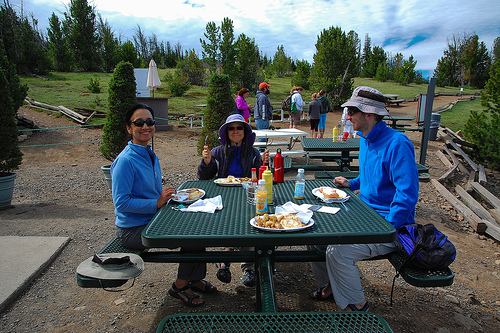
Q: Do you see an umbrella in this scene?
A: Yes, there is an umbrella.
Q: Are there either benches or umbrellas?
A: Yes, there is an umbrella.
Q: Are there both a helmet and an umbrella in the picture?
A: No, there is an umbrella but no helmets.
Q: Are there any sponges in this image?
A: No, there are no sponges.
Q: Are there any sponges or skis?
A: No, there are no sponges or skis.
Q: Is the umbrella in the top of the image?
A: Yes, the umbrella is in the top of the image.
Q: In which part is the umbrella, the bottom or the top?
A: The umbrella is in the top of the image.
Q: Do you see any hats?
A: Yes, there is a hat.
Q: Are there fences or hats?
A: Yes, there is a hat.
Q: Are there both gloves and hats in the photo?
A: No, there is a hat but no gloves.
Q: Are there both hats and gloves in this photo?
A: No, there is a hat but no gloves.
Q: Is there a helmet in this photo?
A: No, there are no helmets.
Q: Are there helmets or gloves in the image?
A: No, there are no helmets or gloves.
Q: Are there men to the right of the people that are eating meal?
A: Yes, there is a man to the right of the people.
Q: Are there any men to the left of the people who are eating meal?
A: No, the man is to the right of the people.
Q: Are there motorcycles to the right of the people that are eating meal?
A: No, there is a man to the right of the people.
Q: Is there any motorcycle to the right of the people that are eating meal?
A: No, there is a man to the right of the people.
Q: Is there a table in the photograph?
A: Yes, there is a table.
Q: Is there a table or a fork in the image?
A: Yes, there is a table.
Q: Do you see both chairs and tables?
A: No, there is a table but no chairs.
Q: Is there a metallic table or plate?
A: Yes, there is a metal table.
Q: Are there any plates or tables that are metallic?
A: Yes, the table is metallic.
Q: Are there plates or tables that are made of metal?
A: Yes, the table is made of metal.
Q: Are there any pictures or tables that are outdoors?
A: Yes, the table is outdoors.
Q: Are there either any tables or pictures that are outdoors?
A: Yes, the table is outdoors.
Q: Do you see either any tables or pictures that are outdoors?
A: Yes, the table is outdoors.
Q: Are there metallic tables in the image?
A: Yes, there is a metal table.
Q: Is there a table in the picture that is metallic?
A: Yes, there is a table that is metallic.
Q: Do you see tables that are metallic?
A: Yes, there is a table that is metallic.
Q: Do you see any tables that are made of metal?
A: Yes, there is a table that is made of metal.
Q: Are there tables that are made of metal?
A: Yes, there is a table that is made of metal.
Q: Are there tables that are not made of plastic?
A: Yes, there is a table that is made of metal.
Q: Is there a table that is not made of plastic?
A: Yes, there is a table that is made of metal.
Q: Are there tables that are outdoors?
A: Yes, there is a table that is outdoors.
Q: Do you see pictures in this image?
A: No, there are no pictures.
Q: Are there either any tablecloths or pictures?
A: No, there are no pictures or tablecloths.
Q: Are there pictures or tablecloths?
A: No, there are no pictures or tablecloths.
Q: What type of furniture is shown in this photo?
A: The furniture is a table.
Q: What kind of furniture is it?
A: The piece of furniture is a table.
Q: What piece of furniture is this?
A: This is a table.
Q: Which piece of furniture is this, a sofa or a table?
A: This is a table.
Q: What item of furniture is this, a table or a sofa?
A: This is a table.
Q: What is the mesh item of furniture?
A: The piece of furniture is a table.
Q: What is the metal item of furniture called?
A: The piece of furniture is a table.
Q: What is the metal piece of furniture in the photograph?
A: The piece of furniture is a table.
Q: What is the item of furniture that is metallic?
A: The piece of furniture is a table.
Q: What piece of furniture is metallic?
A: The piece of furniture is a table.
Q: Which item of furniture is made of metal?
A: The piece of furniture is a table.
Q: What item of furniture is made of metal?
A: The piece of furniture is a table.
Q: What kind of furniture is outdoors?
A: The furniture is a table.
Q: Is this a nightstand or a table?
A: This is a table.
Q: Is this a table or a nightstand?
A: This is a table.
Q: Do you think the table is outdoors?
A: Yes, the table is outdoors.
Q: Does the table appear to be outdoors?
A: Yes, the table is outdoors.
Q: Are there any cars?
A: No, there are no cars.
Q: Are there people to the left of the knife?
A: Yes, there are people to the left of the knife.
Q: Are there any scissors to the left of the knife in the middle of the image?
A: No, there are people to the left of the knife.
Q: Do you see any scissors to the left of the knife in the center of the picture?
A: No, there are people to the left of the knife.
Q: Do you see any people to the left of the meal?
A: Yes, there are people to the left of the meal.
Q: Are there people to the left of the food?
A: Yes, there are people to the left of the food.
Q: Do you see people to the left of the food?
A: Yes, there are people to the left of the food.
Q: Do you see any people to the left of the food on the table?
A: Yes, there are people to the left of the food.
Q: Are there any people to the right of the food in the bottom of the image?
A: No, the people are to the left of the food.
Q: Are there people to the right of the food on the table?
A: No, the people are to the left of the food.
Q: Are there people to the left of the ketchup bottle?
A: Yes, there are people to the left of the bottle.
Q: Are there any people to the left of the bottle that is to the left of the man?
A: Yes, there are people to the left of the bottle.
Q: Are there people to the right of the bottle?
A: No, the people are to the left of the bottle.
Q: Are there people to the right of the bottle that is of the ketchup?
A: No, the people are to the left of the bottle.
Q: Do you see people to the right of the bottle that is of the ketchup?
A: No, the people are to the left of the bottle.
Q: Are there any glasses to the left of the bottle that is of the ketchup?
A: No, there are people to the left of the bottle.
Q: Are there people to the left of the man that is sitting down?
A: Yes, there are people to the left of the man.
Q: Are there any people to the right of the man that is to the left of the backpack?
A: No, the people are to the left of the man.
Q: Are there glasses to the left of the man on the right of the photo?
A: No, there are people to the left of the man.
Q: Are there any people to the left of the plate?
A: Yes, there are people to the left of the plate.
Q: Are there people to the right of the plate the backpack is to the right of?
A: No, the people are to the left of the plate.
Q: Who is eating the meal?
A: The people are eating the meal.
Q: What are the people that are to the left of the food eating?
A: The people are eating meal.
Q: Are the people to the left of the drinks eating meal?
A: Yes, the people are eating meal.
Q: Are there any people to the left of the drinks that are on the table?
A: Yes, there are people to the left of the drinks.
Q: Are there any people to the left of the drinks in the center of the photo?
A: Yes, there are people to the left of the drinks.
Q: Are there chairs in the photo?
A: No, there are no chairs.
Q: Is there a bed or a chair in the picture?
A: No, there are no chairs or beds.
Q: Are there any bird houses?
A: No, there are no bird houses.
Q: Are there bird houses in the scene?
A: No, there are no bird houses.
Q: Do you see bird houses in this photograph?
A: No, there are no bird houses.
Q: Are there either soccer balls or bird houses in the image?
A: No, there are no bird houses or soccer balls.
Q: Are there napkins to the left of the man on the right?
A: Yes, there is a napkin to the left of the man.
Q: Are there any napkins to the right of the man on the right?
A: No, the napkin is to the left of the man.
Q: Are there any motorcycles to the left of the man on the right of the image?
A: No, there is a napkin to the left of the man.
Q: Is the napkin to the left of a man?
A: Yes, the napkin is to the left of a man.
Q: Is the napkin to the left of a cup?
A: No, the napkin is to the left of a man.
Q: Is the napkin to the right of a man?
A: No, the napkin is to the left of a man.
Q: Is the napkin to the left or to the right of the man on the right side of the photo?
A: The napkin is to the left of the man.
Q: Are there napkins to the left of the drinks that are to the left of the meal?
A: Yes, there is a napkin to the left of the drinks.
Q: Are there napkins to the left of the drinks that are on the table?
A: Yes, there is a napkin to the left of the drinks.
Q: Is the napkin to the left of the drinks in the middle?
A: Yes, the napkin is to the left of the drinks.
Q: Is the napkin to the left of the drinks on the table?
A: Yes, the napkin is to the left of the drinks.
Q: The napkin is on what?
A: The napkin is on the table.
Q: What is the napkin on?
A: The napkin is on the table.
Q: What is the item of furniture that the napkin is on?
A: The piece of furniture is a table.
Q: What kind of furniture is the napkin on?
A: The napkin is on the table.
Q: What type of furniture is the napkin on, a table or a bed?
A: The napkin is on a table.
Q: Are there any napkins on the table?
A: Yes, there is a napkin on the table.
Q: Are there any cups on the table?
A: No, there is a napkin on the table.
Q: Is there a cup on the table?
A: No, there is a napkin on the table.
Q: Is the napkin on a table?
A: Yes, the napkin is on a table.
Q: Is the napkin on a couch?
A: No, the napkin is on a table.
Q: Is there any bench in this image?
A: Yes, there is a bench.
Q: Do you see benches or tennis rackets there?
A: Yes, there is a bench.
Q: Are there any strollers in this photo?
A: No, there are no strollers.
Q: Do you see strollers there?
A: No, there are no strollers.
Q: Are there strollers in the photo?
A: No, there are no strollers.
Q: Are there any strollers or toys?
A: No, there are no strollers or toys.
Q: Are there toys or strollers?
A: No, there are no strollers or toys.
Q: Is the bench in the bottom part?
A: Yes, the bench is in the bottom of the image.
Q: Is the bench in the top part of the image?
A: No, the bench is in the bottom of the image.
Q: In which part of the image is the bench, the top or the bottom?
A: The bench is in the bottom of the image.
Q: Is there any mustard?
A: Yes, there is mustard.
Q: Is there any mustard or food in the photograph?
A: Yes, there is mustard.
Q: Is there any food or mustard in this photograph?
A: Yes, there is mustard.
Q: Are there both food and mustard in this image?
A: Yes, there are both mustard and food.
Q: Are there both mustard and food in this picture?
A: Yes, there are both mustard and food.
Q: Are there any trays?
A: No, there are no trays.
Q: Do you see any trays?
A: No, there are no trays.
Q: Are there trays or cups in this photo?
A: No, there are no trays or cups.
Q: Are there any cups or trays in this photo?
A: No, there are no trays or cups.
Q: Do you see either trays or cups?
A: No, there are no trays or cups.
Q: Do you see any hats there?
A: Yes, there is a hat.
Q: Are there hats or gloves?
A: Yes, there is a hat.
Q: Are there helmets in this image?
A: No, there are no helmets.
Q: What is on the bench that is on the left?
A: The hat is on the bench.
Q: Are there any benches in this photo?
A: Yes, there is a bench.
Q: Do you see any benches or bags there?
A: Yes, there is a bench.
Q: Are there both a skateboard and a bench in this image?
A: No, there is a bench but no skateboards.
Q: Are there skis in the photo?
A: No, there are no skis.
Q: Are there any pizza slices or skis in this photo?
A: No, there are no skis or pizza slices.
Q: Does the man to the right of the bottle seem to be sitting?
A: Yes, the man is sitting.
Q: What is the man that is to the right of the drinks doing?
A: The man is sitting.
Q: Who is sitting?
A: The man is sitting.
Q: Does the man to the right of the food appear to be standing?
A: No, the man is sitting.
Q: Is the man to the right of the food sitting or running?
A: The man is sitting.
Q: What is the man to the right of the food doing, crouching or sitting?
A: The man is sitting.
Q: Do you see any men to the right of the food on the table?
A: Yes, there is a man to the right of the food.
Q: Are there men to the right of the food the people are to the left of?
A: Yes, there is a man to the right of the food.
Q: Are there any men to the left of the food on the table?
A: No, the man is to the right of the food.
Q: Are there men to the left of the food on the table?
A: No, the man is to the right of the food.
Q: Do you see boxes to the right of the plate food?
A: No, there is a man to the right of the food.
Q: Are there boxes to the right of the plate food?
A: No, there is a man to the right of the food.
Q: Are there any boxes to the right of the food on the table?
A: No, there is a man to the right of the food.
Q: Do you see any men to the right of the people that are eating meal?
A: Yes, there is a man to the right of the people.